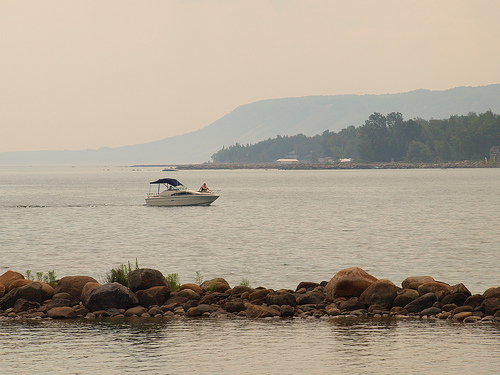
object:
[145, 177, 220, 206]
boat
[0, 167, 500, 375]
bay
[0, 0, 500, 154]
sky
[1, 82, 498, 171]
mountains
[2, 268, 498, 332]
jetty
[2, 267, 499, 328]
rock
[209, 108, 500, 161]
forest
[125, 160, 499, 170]
land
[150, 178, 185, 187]
canvas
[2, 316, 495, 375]
reflection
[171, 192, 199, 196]
windows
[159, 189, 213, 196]
cabin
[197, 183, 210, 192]
person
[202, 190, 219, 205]
front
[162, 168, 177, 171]
island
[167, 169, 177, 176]
middle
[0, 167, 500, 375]
water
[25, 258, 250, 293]
grass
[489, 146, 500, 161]
home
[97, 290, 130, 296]
parts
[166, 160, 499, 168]
edge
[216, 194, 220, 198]
tip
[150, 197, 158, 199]
parts